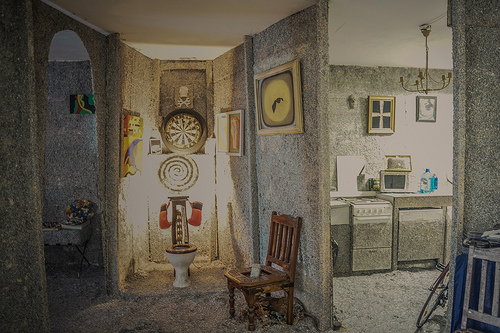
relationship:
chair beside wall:
[223, 207, 303, 330] [213, 2, 333, 331]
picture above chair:
[252, 60, 304, 137] [223, 207, 303, 330]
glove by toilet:
[187, 202, 202, 227] [163, 243, 197, 289]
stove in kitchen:
[340, 196, 393, 274] [330, 0, 450, 330]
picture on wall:
[365, 94, 397, 134] [326, 65, 451, 190]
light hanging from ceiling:
[395, 24, 451, 93] [325, 0, 453, 71]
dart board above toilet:
[165, 112, 200, 149] [163, 243, 197, 289]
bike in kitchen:
[415, 256, 447, 326] [330, 0, 450, 330]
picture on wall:
[415, 95, 436, 121] [326, 65, 451, 190]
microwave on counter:
[377, 171, 409, 195] [375, 193, 449, 198]